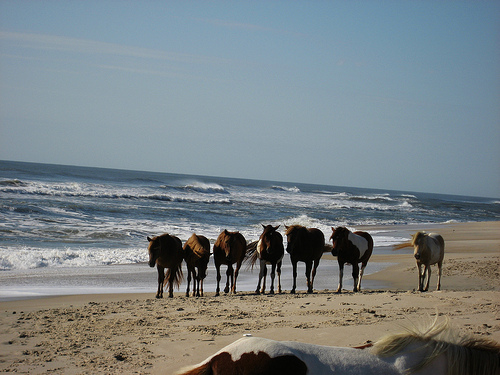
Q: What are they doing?
A: Walking.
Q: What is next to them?
A: The water.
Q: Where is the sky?
A: Above them.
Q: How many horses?
A: 8.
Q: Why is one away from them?
A: Got ahead.